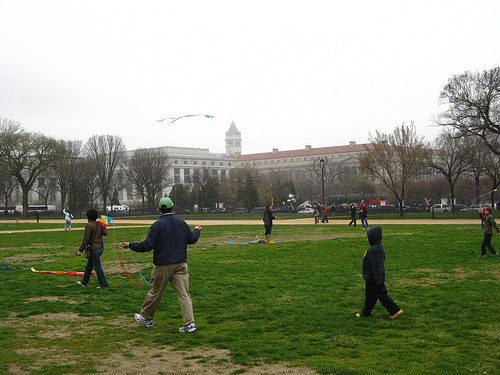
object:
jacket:
[128, 213, 201, 266]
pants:
[81, 247, 109, 287]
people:
[354, 226, 404, 318]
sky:
[4, 2, 496, 159]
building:
[0, 140, 487, 218]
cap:
[366, 226, 383, 246]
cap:
[159, 197, 175, 210]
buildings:
[225, 119, 243, 156]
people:
[358, 199, 370, 230]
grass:
[262, 291, 336, 335]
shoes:
[77, 281, 87, 288]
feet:
[133, 313, 154, 328]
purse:
[84, 244, 92, 259]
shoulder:
[84, 224, 91, 236]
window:
[173, 168, 182, 184]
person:
[63, 207, 74, 232]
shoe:
[179, 322, 197, 332]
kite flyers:
[119, 197, 202, 334]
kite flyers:
[263, 203, 277, 244]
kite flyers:
[76, 209, 111, 290]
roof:
[234, 143, 499, 158]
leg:
[482, 234, 491, 255]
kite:
[155, 114, 214, 125]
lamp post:
[319, 157, 325, 206]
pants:
[140, 261, 194, 326]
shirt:
[479, 213, 500, 236]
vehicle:
[430, 203, 453, 212]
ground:
[1, 213, 499, 373]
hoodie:
[362, 226, 385, 284]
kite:
[226, 235, 279, 246]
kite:
[29, 267, 96, 276]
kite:
[100, 214, 114, 227]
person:
[348, 202, 358, 227]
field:
[0, 211, 500, 374]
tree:
[358, 120, 437, 217]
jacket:
[263, 209, 276, 226]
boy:
[477, 206, 499, 258]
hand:
[119, 242, 129, 249]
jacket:
[79, 219, 108, 252]